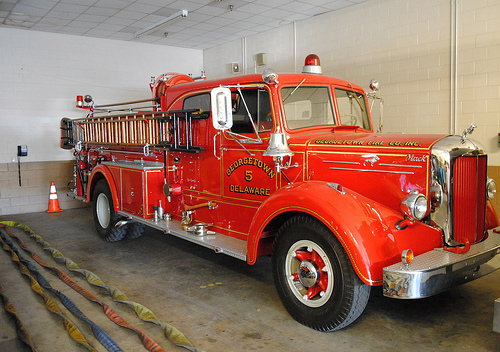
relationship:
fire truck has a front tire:
[57, 54, 500, 335] [269, 214, 371, 336]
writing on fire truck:
[220, 151, 275, 203] [57, 54, 500, 335]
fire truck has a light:
[57, 54, 500, 335] [398, 185, 432, 222]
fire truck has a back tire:
[57, 54, 500, 335] [82, 183, 126, 246]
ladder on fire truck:
[74, 114, 196, 149] [57, 54, 500, 335]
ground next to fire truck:
[136, 258, 196, 299] [57, 54, 500, 335]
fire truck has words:
[57, 54, 500, 335] [312, 134, 424, 152]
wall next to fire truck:
[346, 37, 425, 69] [57, 54, 500, 335]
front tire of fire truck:
[279, 221, 341, 299] [57, 54, 500, 335]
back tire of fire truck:
[82, 183, 126, 246] [57, 54, 500, 335]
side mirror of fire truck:
[207, 85, 235, 133] [57, 54, 500, 335]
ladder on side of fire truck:
[74, 114, 196, 149] [57, 54, 500, 335]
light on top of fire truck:
[398, 185, 432, 222] [57, 54, 500, 335]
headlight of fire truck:
[485, 174, 497, 202] [57, 54, 500, 335]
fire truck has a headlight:
[57, 54, 500, 335] [485, 174, 497, 202]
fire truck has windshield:
[57, 54, 500, 335] [287, 84, 368, 129]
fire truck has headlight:
[57, 54, 500, 335] [485, 174, 497, 202]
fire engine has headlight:
[154, 102, 364, 186] [485, 174, 497, 202]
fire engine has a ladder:
[154, 102, 364, 186] [74, 114, 196, 149]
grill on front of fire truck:
[447, 148, 492, 246] [150, 108, 400, 224]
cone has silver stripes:
[43, 176, 66, 216] [49, 184, 60, 197]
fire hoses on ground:
[14, 226, 153, 351] [136, 258, 196, 299]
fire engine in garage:
[154, 102, 364, 186] [9, 12, 499, 351]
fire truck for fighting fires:
[57, 54, 500, 335] [351, 226, 369, 249]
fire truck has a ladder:
[150, 108, 400, 224] [74, 114, 196, 149]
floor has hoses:
[62, 226, 106, 267] [34, 294, 196, 350]